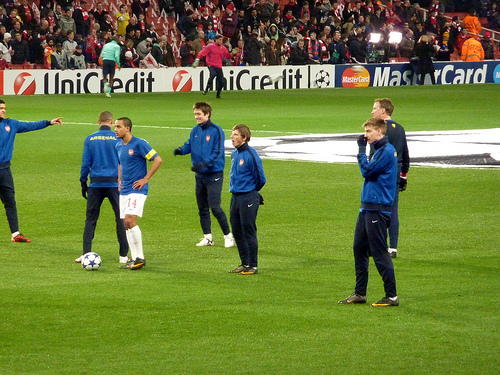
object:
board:
[3, 65, 308, 96]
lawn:
[0, 84, 499, 374]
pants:
[81, 186, 129, 257]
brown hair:
[362, 118, 387, 135]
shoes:
[338, 291, 398, 306]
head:
[362, 117, 388, 144]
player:
[0, 98, 64, 249]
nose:
[362, 132, 368, 138]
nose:
[370, 109, 377, 114]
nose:
[229, 134, 234, 140]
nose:
[114, 127, 118, 132]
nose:
[194, 115, 199, 120]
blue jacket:
[0, 117, 51, 170]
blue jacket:
[79, 124, 120, 187]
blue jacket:
[180, 118, 227, 173]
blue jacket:
[229, 143, 267, 196]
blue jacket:
[357, 135, 399, 215]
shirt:
[113, 134, 159, 196]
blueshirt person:
[335, 118, 398, 307]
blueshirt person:
[227, 124, 266, 276]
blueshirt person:
[173, 102, 237, 250]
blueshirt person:
[113, 117, 164, 271]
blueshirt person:
[73, 111, 132, 264]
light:
[387, 30, 402, 47]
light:
[365, 30, 383, 44]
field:
[0, 0, 499, 375]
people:
[0, 0, 232, 70]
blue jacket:
[356, 135, 399, 211]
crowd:
[250, 0, 499, 62]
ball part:
[81, 251, 103, 270]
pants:
[351, 209, 397, 297]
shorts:
[118, 191, 147, 219]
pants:
[195, 171, 230, 235]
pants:
[229, 190, 260, 268]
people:
[193, 34, 240, 99]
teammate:
[0, 98, 409, 308]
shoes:
[228, 264, 258, 275]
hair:
[193, 102, 212, 118]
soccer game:
[0, 83, 499, 375]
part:
[144, 301, 269, 372]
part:
[87, 254, 97, 268]